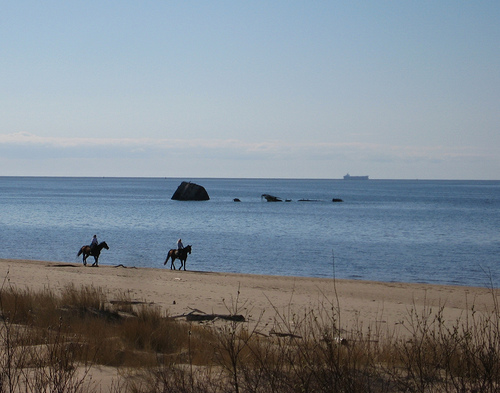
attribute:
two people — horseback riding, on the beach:
[75, 230, 194, 273]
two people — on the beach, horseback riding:
[77, 231, 195, 269]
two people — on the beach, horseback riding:
[76, 234, 194, 277]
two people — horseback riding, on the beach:
[76, 227, 196, 281]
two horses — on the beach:
[77, 233, 194, 275]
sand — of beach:
[245, 277, 497, 335]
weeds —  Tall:
[3, 326, 90, 391]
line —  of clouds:
[2, 131, 498, 143]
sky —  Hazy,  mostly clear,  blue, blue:
[2, 0, 498, 176]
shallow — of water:
[5, 202, 495, 245]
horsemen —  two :
[78, 237, 194, 271]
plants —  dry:
[216, 328, 497, 386]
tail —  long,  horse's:
[165, 246, 174, 264]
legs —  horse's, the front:
[94, 253, 101, 269]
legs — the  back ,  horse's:
[80, 250, 89, 264]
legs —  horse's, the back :
[80, 253, 87, 267]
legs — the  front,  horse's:
[93, 250, 102, 270]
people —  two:
[91, 233, 101, 258]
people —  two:
[85, 231, 99, 251]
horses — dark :
[73, 232, 201, 277]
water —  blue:
[4, 173, 484, 287]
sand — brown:
[7, 263, 437, 337]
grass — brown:
[5, 292, 473, 383]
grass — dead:
[11, 290, 480, 390]